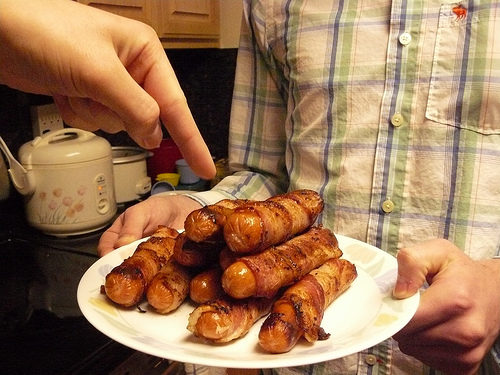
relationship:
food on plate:
[121, 208, 336, 333] [340, 292, 388, 347]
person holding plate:
[260, 19, 489, 311] [340, 292, 388, 347]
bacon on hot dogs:
[252, 195, 260, 244] [105, 267, 212, 315]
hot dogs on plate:
[105, 267, 212, 315] [340, 292, 388, 347]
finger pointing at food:
[125, 54, 214, 191] [121, 208, 336, 333]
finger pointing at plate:
[125, 54, 214, 191] [340, 292, 388, 347]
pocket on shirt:
[427, 0, 493, 132] [297, 95, 397, 155]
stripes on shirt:
[296, 53, 381, 95] [297, 95, 397, 155]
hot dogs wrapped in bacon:
[105, 267, 212, 315] [252, 195, 260, 244]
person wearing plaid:
[260, 19, 489, 311] [237, 15, 275, 52]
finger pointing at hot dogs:
[125, 54, 214, 191] [105, 267, 212, 315]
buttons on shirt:
[382, 17, 431, 127] [297, 95, 397, 155]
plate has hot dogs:
[340, 292, 388, 347] [105, 267, 212, 315]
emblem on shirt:
[450, 0, 471, 30] [297, 95, 397, 155]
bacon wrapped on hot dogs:
[252, 195, 260, 244] [105, 267, 212, 315]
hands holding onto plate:
[87, 204, 481, 351] [340, 292, 388, 347]